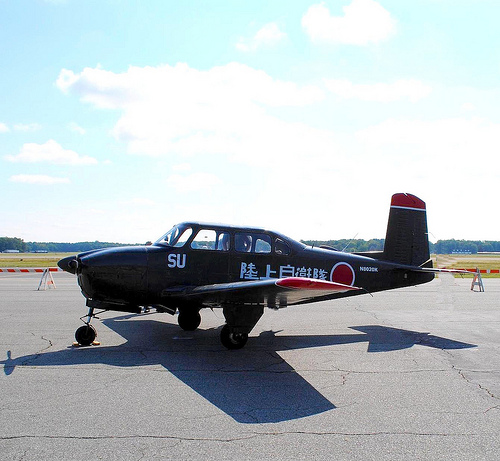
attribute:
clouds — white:
[298, 1, 398, 61]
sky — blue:
[2, 1, 499, 281]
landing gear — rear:
[216, 308, 267, 353]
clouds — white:
[50, 42, 460, 189]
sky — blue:
[0, 2, 498, 197]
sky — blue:
[305, 32, 457, 128]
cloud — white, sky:
[301, 1, 406, 48]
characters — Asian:
[238, 260, 332, 285]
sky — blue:
[5, 9, 473, 193]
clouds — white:
[54, 62, 334, 119]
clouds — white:
[237, 22, 286, 58]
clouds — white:
[301, 0, 393, 49]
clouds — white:
[7, 139, 98, 166]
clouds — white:
[10, 172, 71, 187]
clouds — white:
[26, 53, 324, 193]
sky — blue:
[0, 0, 499, 241]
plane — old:
[57, 192, 480, 344]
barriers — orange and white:
[9, 265, 59, 274]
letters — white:
[164, 250, 189, 270]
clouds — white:
[55, 65, 303, 172]